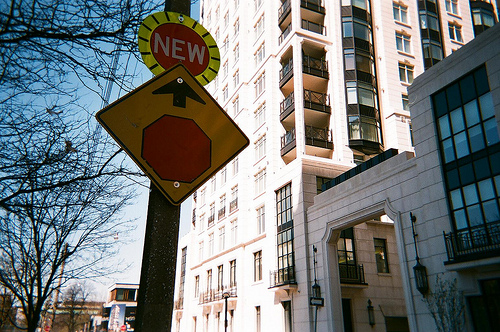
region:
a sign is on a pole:
[99, 63, 248, 193]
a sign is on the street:
[96, 61, 238, 208]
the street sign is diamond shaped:
[101, 63, 256, 208]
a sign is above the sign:
[136, 10, 224, 87]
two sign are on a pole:
[107, 10, 254, 212]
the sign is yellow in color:
[93, 60, 253, 202]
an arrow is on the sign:
[158, 75, 204, 113]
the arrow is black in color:
[158, 78, 201, 110]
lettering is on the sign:
[151, 29, 210, 66]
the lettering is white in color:
[153, 30, 208, 69]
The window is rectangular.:
[429, 83, 450, 118]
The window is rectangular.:
[442, 75, 465, 115]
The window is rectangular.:
[456, 68, 481, 108]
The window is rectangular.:
[468, 55, 493, 102]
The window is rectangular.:
[433, 107, 452, 144]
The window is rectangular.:
[446, 103, 468, 138]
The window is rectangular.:
[459, 95, 483, 131]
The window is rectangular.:
[473, 88, 498, 123]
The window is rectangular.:
[437, 132, 457, 168]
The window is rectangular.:
[448, 125, 474, 162]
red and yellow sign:
[106, 81, 223, 216]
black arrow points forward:
[135, 74, 189, 113]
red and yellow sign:
[141, 9, 205, 70]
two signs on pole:
[150, 14, 202, 329]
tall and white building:
[182, 2, 427, 323]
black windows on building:
[249, 195, 306, 287]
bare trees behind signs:
[4, 15, 107, 298]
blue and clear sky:
[5, 4, 79, 169]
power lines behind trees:
[77, 0, 151, 176]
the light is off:
[408, 261, 429, 296]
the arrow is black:
[167, 79, 192, 100]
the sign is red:
[165, 132, 189, 162]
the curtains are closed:
[356, 122, 375, 134]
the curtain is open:
[347, 28, 367, 42]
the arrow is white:
[308, 297, 324, 305]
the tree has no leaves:
[24, 130, 76, 185]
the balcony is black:
[306, 55, 323, 73]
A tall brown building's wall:
[207, 154, 299, 321]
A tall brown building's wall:
[222, 11, 293, 101]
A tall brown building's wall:
[324, 1, 391, 116]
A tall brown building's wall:
[176, 281, 268, 326]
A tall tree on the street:
[56, 279, 93, 325]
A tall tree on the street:
[1, 123, 108, 317]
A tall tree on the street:
[4, 1, 189, 101]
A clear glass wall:
[430, 94, 499, 147]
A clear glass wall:
[455, 154, 495, 225]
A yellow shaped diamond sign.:
[111, 73, 246, 190]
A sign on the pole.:
[127, 18, 225, 83]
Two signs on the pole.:
[117, 18, 249, 196]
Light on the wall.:
[402, 254, 439, 299]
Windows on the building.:
[193, 255, 250, 286]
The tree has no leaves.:
[13, 125, 121, 257]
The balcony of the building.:
[269, 40, 328, 88]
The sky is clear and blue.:
[3, 11, 125, 153]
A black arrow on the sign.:
[162, 57, 205, 114]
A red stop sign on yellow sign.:
[136, 113, 224, 185]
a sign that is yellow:
[88, 55, 240, 208]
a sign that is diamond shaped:
[86, 55, 278, 219]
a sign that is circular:
[142, 23, 247, 98]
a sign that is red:
[152, 18, 209, 73]